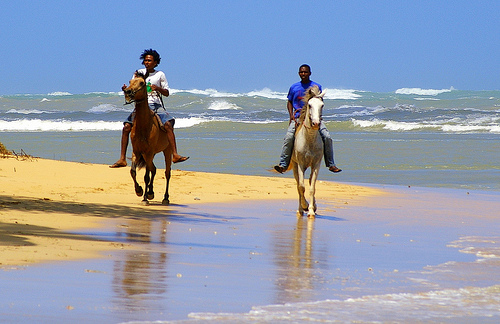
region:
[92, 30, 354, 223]
the people are riding horses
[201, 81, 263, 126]
the ocean is turbulant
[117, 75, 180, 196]
the horse is brown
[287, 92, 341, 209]
the horse is white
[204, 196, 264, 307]
the sand is wet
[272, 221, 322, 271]
the reflection is in the sand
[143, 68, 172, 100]
the woman is wearing a white shirt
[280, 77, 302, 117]
the man is wearing a blue shirt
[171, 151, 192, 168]
the woman is wearing a flip-flop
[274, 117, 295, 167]
the jeans are blue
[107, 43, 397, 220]
Two people riding horses.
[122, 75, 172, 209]
Brown horse walking.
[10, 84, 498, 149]
Ocean behind horses.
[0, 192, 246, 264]
Shadows of trees on sand.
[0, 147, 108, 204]
Tan sand on beach.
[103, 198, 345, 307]
Reflections of horses on water.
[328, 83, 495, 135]
White capped waves.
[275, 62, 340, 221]
Man in blue shirt riding horse.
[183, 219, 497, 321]
Water washing up on sand.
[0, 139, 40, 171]
Dry vegetation on beach.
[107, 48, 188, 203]
Person and horse on beach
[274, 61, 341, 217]
Person and horse on beach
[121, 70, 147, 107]
Head of horse on beach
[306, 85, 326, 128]
Head of horse on beach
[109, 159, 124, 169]
Foot of riiding person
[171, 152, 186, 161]
foot of person riding on beach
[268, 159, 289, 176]
Foot of person riding on beach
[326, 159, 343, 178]
Foot of person riding on beach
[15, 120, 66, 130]
White churning surf water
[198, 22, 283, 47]
Clear blue ocean sky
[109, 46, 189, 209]
PERSON AND HORSE RIDING ON BEACH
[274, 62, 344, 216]
PERSON AND HORSE RIDING ON BEACH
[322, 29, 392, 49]
Cleare blue ocean sky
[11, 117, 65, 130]
Churning white surf water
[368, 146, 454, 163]
Green ocean beach water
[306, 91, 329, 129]
Head of beach horse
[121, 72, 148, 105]
Head of beach horse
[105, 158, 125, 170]
Foot of person riding horse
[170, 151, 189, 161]
Foot of person riding horse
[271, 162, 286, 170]
Foot of person riding horse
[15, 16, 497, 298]
photograph taken on the beach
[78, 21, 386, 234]
two people riding horses on the beach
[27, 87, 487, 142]
many waves in the ocean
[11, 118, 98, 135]
white foam from crashing waves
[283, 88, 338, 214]
solid white horse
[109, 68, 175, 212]
small brown horse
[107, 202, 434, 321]
wet shiiny sand from ocean water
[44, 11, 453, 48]
bright clear blue sky with no clouds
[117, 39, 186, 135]
boy wearing jean shorts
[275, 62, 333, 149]
man wearing a blue t-shirt